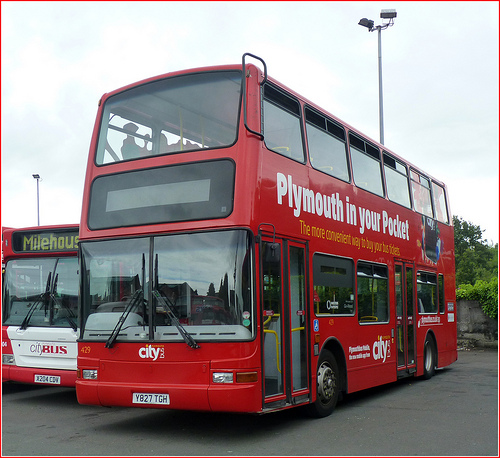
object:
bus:
[74, 54, 463, 423]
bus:
[2, 224, 80, 392]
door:
[256, 229, 288, 411]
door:
[393, 258, 404, 376]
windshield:
[73, 225, 257, 342]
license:
[132, 394, 172, 404]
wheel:
[305, 352, 340, 417]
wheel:
[423, 331, 439, 377]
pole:
[376, 33, 384, 147]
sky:
[0, 2, 497, 253]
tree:
[445, 213, 497, 321]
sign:
[8, 227, 81, 256]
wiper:
[145, 288, 203, 352]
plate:
[28, 373, 63, 386]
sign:
[274, 168, 409, 241]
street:
[0, 344, 497, 457]